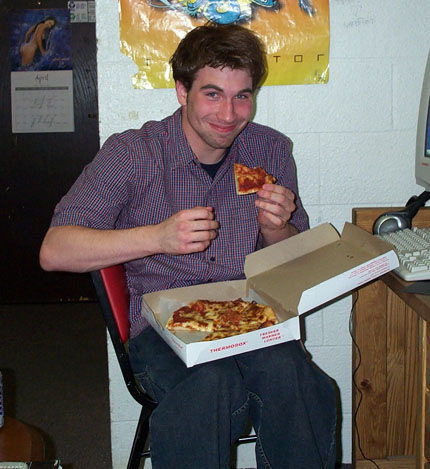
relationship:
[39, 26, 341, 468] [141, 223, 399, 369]
man holding pizzabox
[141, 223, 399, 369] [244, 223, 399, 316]
pizzabox with open lid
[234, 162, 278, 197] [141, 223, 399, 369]
pizza slice removed from pizzabox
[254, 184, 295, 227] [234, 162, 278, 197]
hand holding pizza slice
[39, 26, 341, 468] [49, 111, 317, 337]
man wearing shirt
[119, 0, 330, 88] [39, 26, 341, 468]
poster behind man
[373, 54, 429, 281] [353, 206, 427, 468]
computer on desk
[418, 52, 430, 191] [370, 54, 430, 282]
monitor on computer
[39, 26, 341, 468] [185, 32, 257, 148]
man has head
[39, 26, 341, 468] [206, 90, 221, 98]
man has eyes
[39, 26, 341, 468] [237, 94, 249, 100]
man has eyes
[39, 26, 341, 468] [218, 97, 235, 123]
man has nose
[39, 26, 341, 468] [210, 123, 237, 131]
man has mouth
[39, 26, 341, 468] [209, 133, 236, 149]
man has chin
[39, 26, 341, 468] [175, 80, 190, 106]
man has ear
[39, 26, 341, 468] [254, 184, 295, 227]
man has hand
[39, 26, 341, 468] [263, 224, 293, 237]
man has wrist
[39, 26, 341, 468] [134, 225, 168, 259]
man has wrist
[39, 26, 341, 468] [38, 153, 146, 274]
man has arm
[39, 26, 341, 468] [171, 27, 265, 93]
man has hair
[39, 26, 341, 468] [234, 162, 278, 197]
man has pizza slice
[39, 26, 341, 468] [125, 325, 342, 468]
man wearing jeans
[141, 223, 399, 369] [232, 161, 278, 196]
pizzabox missing pizza slice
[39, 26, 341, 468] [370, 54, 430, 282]
man has computer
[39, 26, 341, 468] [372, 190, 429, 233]
man has headphones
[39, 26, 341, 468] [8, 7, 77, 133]
man has calendar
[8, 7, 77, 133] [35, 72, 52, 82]
calendar showing april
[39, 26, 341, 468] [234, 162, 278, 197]
man eating pizza slice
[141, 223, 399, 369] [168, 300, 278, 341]
pizzabox has pizza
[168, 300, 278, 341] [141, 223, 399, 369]
paper in pizzabox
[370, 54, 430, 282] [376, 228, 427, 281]
computer has keyboard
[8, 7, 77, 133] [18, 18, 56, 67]
calendar has woman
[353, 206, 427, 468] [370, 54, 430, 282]
desk under computer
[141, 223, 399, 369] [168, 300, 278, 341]
pizzabox contains pizza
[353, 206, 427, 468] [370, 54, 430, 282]
desk holding computer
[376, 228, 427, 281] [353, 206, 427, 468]
keyboard on desk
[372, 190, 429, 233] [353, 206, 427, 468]
headphones on desk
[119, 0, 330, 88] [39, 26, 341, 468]
poster on wall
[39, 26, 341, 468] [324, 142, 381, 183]
wall made of concrete blocks